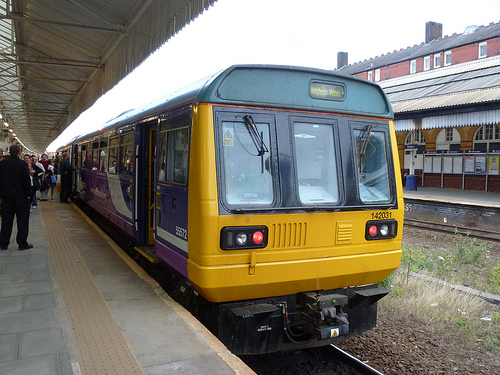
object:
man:
[0, 144, 34, 251]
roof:
[337, 20, 500, 83]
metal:
[327, 342, 388, 374]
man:
[59, 152, 78, 204]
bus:
[58, 64, 405, 355]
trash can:
[406, 175, 419, 191]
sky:
[220, 8, 331, 55]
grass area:
[409, 234, 496, 332]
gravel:
[385, 320, 452, 372]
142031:
[371, 212, 392, 220]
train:
[54, 61, 406, 357]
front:
[196, 61, 406, 355]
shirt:
[38, 159, 48, 170]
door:
[137, 118, 159, 261]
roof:
[376, 55, 500, 114]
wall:
[342, 19, 499, 89]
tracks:
[402, 217, 500, 243]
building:
[337, 21, 500, 198]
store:
[392, 108, 500, 189]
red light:
[253, 231, 264, 244]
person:
[44, 159, 57, 200]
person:
[23, 154, 43, 209]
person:
[31, 157, 46, 200]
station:
[3, 3, 495, 373]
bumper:
[186, 249, 401, 290]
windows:
[56, 131, 136, 181]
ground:
[318, 225, 499, 372]